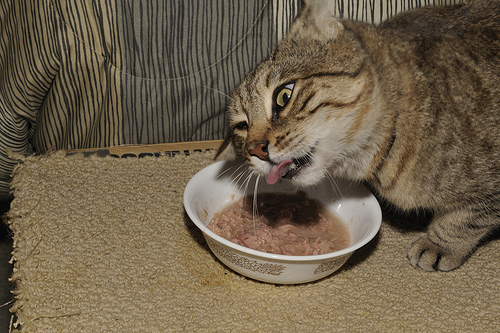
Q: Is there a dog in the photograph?
A: No, there are no dogs.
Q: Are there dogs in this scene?
A: No, there are no dogs.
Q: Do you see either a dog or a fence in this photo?
A: No, there are no dogs or fences.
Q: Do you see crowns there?
A: No, there are no crowns.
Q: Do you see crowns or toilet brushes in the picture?
A: No, there are no crowns or toilet brushes.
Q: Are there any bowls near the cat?
A: Yes, there is a bowl near the cat.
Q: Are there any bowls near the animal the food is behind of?
A: Yes, there is a bowl near the cat.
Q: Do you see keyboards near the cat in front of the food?
A: No, there is a bowl near the cat.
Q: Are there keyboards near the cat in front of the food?
A: No, there is a bowl near the cat.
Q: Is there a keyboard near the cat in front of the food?
A: No, there is a bowl near the cat.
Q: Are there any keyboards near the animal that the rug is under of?
A: No, there is a bowl near the cat.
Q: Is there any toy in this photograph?
A: No, there are no toys.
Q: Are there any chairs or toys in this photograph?
A: No, there are no toys or chairs.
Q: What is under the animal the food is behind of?
A: The rug is under the cat.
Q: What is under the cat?
A: The rug is under the cat.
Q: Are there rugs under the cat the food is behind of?
A: Yes, there is a rug under the cat.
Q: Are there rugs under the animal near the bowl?
A: Yes, there is a rug under the cat.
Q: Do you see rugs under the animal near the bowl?
A: Yes, there is a rug under the cat.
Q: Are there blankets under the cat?
A: No, there is a rug under the cat.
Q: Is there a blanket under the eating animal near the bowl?
A: No, there is a rug under the cat.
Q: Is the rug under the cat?
A: Yes, the rug is under the cat.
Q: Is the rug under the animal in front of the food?
A: Yes, the rug is under the cat.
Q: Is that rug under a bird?
A: No, the rug is under the cat.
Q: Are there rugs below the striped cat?
A: Yes, there is a rug below the cat.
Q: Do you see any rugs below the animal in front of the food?
A: Yes, there is a rug below the cat.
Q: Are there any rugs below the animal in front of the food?
A: Yes, there is a rug below the cat.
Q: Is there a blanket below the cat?
A: No, there is a rug below the cat.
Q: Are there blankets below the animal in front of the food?
A: No, there is a rug below the cat.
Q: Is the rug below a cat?
A: Yes, the rug is below a cat.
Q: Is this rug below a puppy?
A: No, the rug is below a cat.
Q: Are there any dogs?
A: No, there are no dogs.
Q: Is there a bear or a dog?
A: No, there are no dogs or bears.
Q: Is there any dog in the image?
A: No, there are no dogs.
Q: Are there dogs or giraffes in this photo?
A: No, there are no dogs or giraffes.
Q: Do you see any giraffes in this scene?
A: No, there are no giraffes.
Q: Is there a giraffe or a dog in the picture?
A: No, there are no giraffes or dogs.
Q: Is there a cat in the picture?
A: Yes, there is a cat.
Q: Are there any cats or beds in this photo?
A: Yes, there is a cat.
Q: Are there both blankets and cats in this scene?
A: No, there is a cat but no blankets.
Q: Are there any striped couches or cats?
A: Yes, there is a striped cat.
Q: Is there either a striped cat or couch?
A: Yes, there is a striped cat.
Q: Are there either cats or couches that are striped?
A: Yes, the cat is striped.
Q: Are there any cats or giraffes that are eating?
A: Yes, the cat is eating.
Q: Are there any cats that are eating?
A: Yes, there is a cat that is eating.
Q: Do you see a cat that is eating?
A: Yes, there is a cat that is eating.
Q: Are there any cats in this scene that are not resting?
A: Yes, there is a cat that is eating.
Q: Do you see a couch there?
A: No, there are no couches.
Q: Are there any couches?
A: No, there are no couches.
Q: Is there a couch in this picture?
A: No, there are no couches.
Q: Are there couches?
A: No, there are no couches.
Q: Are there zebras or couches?
A: No, there are no couches or zebras.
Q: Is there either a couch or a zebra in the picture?
A: No, there are no couches or zebras.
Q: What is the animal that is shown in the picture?
A: The animal is a cat.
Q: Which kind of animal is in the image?
A: The animal is a cat.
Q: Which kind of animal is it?
A: The animal is a cat.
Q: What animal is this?
A: This is a cat.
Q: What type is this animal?
A: This is a cat.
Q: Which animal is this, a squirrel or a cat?
A: This is a cat.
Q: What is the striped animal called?
A: The animal is a cat.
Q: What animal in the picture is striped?
A: The animal is a cat.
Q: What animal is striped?
A: The animal is a cat.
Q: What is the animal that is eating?
A: The animal is a cat.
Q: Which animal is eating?
A: The animal is a cat.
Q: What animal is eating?
A: The animal is a cat.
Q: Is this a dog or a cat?
A: This is a cat.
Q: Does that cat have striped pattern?
A: Yes, the cat is striped.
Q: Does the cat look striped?
A: Yes, the cat is striped.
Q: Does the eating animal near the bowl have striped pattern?
A: Yes, the cat is striped.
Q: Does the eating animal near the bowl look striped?
A: Yes, the cat is striped.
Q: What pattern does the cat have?
A: The cat has striped pattern.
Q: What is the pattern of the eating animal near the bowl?
A: The cat is striped.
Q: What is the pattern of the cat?
A: The cat is striped.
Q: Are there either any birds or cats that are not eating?
A: No, there is a cat but it is eating.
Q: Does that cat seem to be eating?
A: Yes, the cat is eating.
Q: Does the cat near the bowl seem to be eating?
A: Yes, the cat is eating.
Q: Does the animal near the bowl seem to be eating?
A: Yes, the cat is eating.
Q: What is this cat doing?
A: The cat is eating.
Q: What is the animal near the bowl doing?
A: The cat is eating.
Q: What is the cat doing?
A: The cat is eating.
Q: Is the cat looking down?
A: No, the cat is eating.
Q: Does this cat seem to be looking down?
A: No, the cat is eating.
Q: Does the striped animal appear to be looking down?
A: No, the cat is eating.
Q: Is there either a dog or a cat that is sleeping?
A: No, there is a cat but it is eating.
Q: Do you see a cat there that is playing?
A: No, there is a cat but it is eating.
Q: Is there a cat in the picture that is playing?
A: No, there is a cat but it is eating.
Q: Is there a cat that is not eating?
A: No, there is a cat but it is eating.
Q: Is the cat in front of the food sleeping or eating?
A: The cat is eating.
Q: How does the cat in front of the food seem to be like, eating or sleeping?
A: The cat is eating.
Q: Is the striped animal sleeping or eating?
A: The cat is eating.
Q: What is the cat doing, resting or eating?
A: The cat is eating.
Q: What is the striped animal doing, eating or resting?
A: The cat is eating.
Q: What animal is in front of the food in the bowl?
A: The cat is in front of the food.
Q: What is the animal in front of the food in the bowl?
A: The animal is a cat.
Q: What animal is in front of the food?
A: The animal is a cat.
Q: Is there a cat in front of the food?
A: Yes, there is a cat in front of the food.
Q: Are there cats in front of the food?
A: Yes, there is a cat in front of the food.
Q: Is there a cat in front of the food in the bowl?
A: Yes, there is a cat in front of the food.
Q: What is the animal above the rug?
A: The animal is a cat.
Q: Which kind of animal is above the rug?
A: The animal is a cat.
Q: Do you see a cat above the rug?
A: Yes, there is a cat above the rug.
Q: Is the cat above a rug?
A: Yes, the cat is above a rug.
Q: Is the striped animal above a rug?
A: Yes, the cat is above a rug.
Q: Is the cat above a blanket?
A: No, the cat is above a rug.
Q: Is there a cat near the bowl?
A: Yes, there is a cat near the bowl.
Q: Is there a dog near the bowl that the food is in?
A: No, there is a cat near the bowl.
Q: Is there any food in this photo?
A: Yes, there is food.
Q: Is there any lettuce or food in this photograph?
A: Yes, there is food.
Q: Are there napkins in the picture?
A: No, there are no napkins.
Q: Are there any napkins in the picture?
A: No, there are no napkins.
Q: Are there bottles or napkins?
A: No, there are no napkins or bottles.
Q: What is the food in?
A: The food is in the bowl.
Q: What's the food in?
A: The food is in the bowl.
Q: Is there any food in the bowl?
A: Yes, there is food in the bowl.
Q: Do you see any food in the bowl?
A: Yes, there is food in the bowl.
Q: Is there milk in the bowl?
A: No, there is food in the bowl.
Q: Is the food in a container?
A: No, the food is in the bowl.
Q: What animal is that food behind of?
A: The food is behind the cat.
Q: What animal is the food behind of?
A: The food is behind the cat.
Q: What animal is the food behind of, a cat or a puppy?
A: The food is behind a cat.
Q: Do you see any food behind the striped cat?
A: Yes, there is food behind the cat.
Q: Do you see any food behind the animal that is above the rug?
A: Yes, there is food behind the cat.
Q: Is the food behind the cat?
A: Yes, the food is behind the cat.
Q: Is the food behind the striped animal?
A: Yes, the food is behind the cat.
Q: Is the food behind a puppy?
A: No, the food is behind the cat.